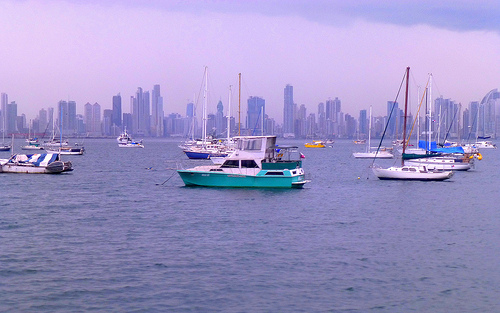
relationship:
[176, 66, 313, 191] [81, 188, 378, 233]
boat on water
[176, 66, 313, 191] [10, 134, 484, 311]
boat on water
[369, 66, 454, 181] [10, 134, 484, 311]
boat on water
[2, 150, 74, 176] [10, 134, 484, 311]
boat on water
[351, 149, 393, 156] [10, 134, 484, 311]
boat on water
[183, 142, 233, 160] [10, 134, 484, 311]
boat on water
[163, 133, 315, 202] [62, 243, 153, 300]
boat on water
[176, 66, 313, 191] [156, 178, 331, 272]
boat on water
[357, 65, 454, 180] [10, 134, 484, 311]
boat on water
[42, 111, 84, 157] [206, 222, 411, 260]
boat on water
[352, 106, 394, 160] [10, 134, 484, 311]
boat on water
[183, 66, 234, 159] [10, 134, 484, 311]
boat on water